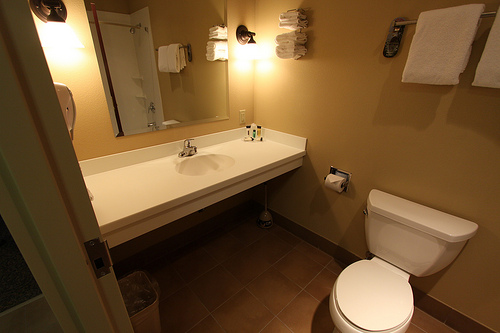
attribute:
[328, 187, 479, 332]
toilet — white, porcelain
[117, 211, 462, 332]
tile floor — brown, tan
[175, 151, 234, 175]
sink — white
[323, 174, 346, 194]
toilet paper — rolled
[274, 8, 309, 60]
towels — folded, shelved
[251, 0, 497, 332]
wall — tan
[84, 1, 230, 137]
mirror — large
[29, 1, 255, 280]
wall — yellow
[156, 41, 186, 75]
towels — hanging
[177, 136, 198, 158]
faucet — chrome, silver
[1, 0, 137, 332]
door frame — white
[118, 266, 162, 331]
trashcan — white, brown, empty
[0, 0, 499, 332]
bathroom — tidy, clean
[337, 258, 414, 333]
lid — closed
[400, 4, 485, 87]
towel — white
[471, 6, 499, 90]
towel — white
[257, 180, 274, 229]
toilet brush — white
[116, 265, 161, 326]
liner — plastic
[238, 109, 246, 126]
light switch — beige